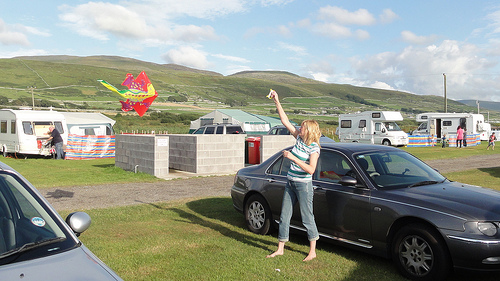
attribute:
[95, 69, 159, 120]
kite — multicolored 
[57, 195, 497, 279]
landscape — grassy , back drop.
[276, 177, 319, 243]
jeans — BLUE 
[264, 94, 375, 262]
lady — pink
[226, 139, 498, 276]
car — BLACK 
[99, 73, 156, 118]
kite — multi colored, airbourne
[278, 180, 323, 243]
jeans — blue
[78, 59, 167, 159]
kite — rainbow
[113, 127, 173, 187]
gray wall — gray brick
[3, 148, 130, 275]
car — silver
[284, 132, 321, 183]
shirt — striped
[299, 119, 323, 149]
hair — blonde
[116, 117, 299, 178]
structure — block, unpainted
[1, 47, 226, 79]
mountain top — grassy, green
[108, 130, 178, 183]
wall — concrete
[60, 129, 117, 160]
fence — blue stripe , red , plastic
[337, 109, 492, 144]
campers — in backgruond, RV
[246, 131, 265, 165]
bin — red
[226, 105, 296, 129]
roof — green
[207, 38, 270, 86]
string — white.,  kite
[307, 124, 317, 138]
hair. — blond 